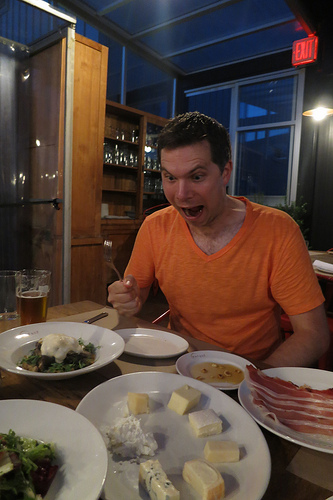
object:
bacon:
[247, 363, 333, 435]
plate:
[239, 365, 333, 452]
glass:
[16, 268, 51, 326]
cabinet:
[102, 101, 144, 219]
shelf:
[104, 163, 139, 169]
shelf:
[104, 135, 139, 145]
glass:
[104, 149, 112, 163]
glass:
[113, 145, 120, 164]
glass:
[129, 153, 135, 166]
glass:
[131, 130, 135, 142]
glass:
[116, 130, 124, 140]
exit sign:
[292, 36, 318, 65]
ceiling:
[53, 0, 333, 77]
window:
[234, 126, 292, 204]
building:
[0, 0, 333, 299]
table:
[0, 300, 333, 499]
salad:
[19, 335, 97, 375]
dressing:
[41, 333, 82, 363]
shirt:
[124, 196, 324, 359]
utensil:
[83, 312, 107, 323]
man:
[108, 112, 329, 369]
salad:
[0, 430, 56, 500]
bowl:
[0, 397, 106, 500]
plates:
[0, 322, 124, 379]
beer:
[16, 290, 47, 324]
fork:
[103, 240, 140, 308]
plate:
[113, 328, 189, 358]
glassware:
[129, 153, 133, 166]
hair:
[158, 113, 232, 174]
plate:
[176, 350, 257, 391]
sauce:
[196, 363, 244, 384]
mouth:
[180, 205, 204, 221]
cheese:
[128, 393, 146, 413]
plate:
[73, 369, 270, 499]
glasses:
[120, 152, 127, 166]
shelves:
[102, 188, 137, 192]